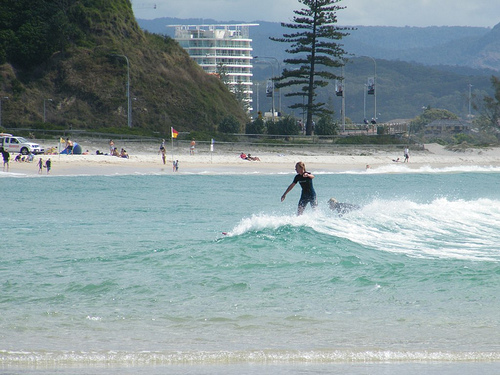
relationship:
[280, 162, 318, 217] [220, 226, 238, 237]
girl standing on surfboard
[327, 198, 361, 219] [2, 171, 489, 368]
guy surfing in water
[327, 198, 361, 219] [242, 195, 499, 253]
guy engulfed by wave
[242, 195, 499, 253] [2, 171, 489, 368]
wave formed in water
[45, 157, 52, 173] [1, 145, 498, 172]
person walking on beach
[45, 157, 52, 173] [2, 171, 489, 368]
person walking near water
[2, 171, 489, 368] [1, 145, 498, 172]
water crashing on beach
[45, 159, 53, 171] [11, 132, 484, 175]
person walking beach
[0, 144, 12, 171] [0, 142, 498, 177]
person walking beach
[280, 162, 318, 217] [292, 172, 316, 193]
girl wearing top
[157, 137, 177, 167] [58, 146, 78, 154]
male wearing shorts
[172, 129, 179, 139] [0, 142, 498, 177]
flag flying beach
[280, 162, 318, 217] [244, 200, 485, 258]
girl ride wave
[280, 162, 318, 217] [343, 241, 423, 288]
girl surfing water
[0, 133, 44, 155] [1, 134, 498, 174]
truck parked beach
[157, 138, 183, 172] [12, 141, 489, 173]
lady walking beach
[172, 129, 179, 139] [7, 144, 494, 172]
flag in sand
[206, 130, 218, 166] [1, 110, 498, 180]
sign on beach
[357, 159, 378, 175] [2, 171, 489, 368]
person in water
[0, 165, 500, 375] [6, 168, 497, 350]
wave in ocean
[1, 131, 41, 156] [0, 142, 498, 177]
truck in beach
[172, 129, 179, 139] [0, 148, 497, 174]
flag in beach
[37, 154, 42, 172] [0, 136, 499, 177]
person in beach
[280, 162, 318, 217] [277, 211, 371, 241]
girl on surfboard.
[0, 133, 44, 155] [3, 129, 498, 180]
truck on beach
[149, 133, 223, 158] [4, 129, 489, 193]
people on beach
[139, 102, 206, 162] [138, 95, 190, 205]
flag on beach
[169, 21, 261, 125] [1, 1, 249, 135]
building behind hill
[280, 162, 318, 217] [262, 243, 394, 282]
girl in water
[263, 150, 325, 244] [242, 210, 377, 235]
girl on surfboard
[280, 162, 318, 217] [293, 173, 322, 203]
girl wearing wetsuit